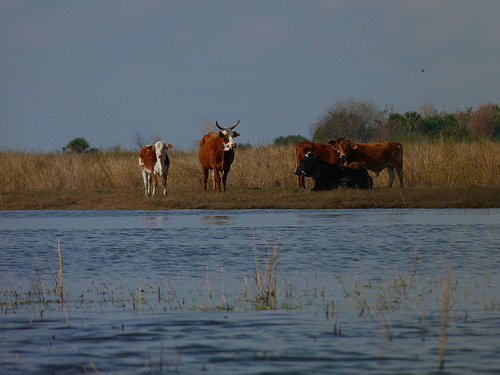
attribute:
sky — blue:
[38, 14, 368, 51]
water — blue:
[31, 215, 432, 284]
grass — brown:
[11, 148, 132, 197]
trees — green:
[324, 98, 498, 153]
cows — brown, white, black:
[136, 110, 416, 202]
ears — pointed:
[226, 125, 247, 138]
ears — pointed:
[142, 141, 182, 151]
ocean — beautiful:
[4, 207, 498, 355]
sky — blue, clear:
[25, 3, 457, 87]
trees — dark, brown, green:
[311, 82, 495, 152]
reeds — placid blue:
[267, 130, 470, 184]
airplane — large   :
[328, 65, 386, 72]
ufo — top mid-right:
[364, 304, 406, 326]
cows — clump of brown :
[293, 124, 417, 194]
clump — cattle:
[314, 128, 436, 178]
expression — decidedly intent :
[195, 119, 253, 168]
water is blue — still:
[4, 207, 500, 372]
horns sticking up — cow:
[215, 117, 243, 131]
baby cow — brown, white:
[135, 140, 179, 199]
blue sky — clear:
[5, 1, 499, 144]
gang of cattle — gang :
[294, 133, 409, 195]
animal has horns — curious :
[193, 116, 244, 196]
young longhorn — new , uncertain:
[135, 133, 177, 195]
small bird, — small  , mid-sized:
[417, 61, 429, 76]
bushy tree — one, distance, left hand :
[63, 135, 95, 154]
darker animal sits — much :
[295, 150, 376, 191]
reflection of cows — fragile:
[141, 204, 415, 237]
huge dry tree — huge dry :
[304, 97, 395, 138]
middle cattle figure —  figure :
[196, 118, 246, 193]